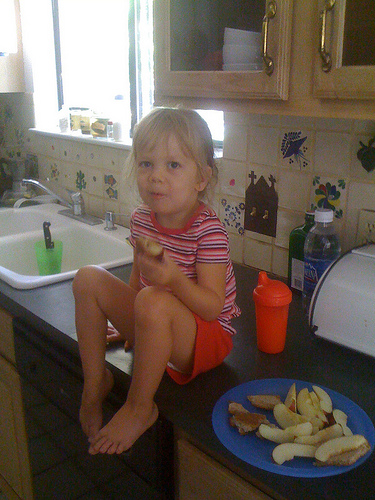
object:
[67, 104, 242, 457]
girl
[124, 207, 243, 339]
shirt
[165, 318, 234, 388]
shorts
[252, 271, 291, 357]
cup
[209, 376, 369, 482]
plate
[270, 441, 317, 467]
apples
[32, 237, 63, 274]
cup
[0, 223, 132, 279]
sink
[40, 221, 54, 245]
knife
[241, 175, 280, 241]
light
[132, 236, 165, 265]
food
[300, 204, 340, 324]
bottle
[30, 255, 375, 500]
counter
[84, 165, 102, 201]
tile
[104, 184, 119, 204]
fish